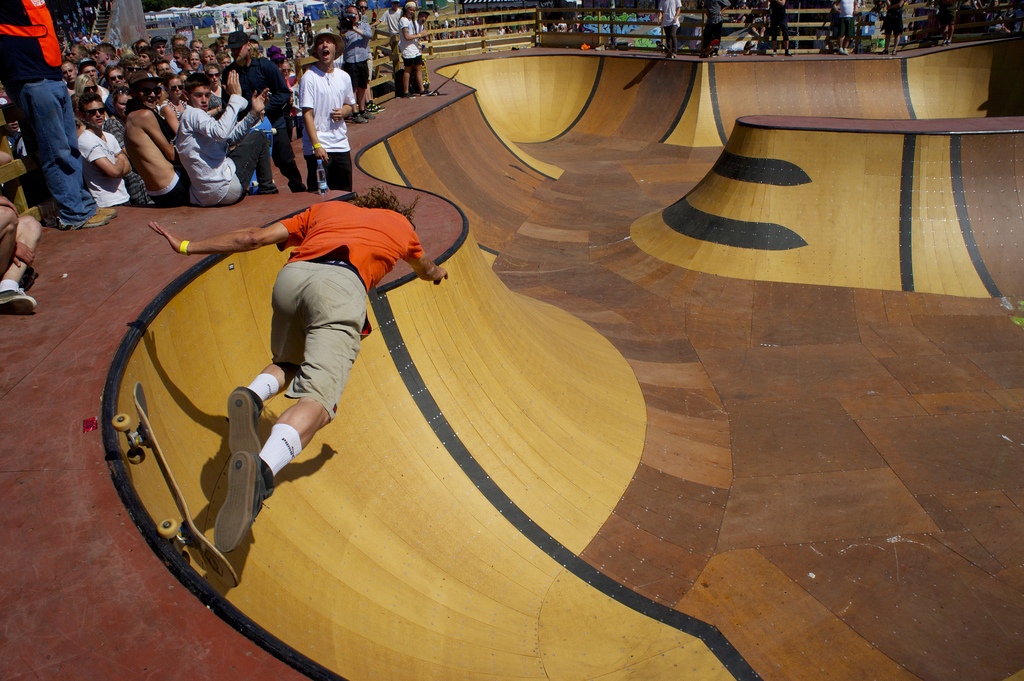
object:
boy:
[142, 184, 448, 553]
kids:
[174, 76, 270, 210]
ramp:
[629, 110, 1023, 302]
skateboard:
[109, 381, 240, 589]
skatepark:
[0, 0, 1024, 680]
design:
[660, 148, 814, 252]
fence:
[364, 0, 959, 106]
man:
[0, 0, 121, 229]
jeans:
[5, 75, 101, 229]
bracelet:
[179, 239, 192, 257]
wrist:
[177, 238, 194, 257]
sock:
[259, 423, 304, 475]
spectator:
[121, 70, 192, 209]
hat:
[128, 69, 165, 88]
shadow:
[131, 308, 345, 602]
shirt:
[280, 200, 424, 293]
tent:
[190, 0, 251, 39]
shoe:
[225, 388, 266, 457]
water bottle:
[316, 159, 330, 196]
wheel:
[111, 413, 132, 432]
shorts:
[270, 261, 368, 419]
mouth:
[320, 48, 331, 58]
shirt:
[299, 66, 357, 155]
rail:
[97, 201, 364, 680]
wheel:
[156, 518, 181, 540]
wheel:
[126, 445, 147, 464]